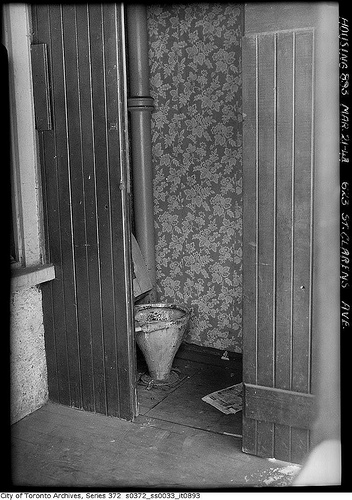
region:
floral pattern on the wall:
[166, 147, 236, 266]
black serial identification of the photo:
[0, 490, 214, 498]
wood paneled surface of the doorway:
[266, 277, 321, 405]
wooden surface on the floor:
[70, 420, 202, 481]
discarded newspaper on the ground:
[201, 382, 239, 422]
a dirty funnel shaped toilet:
[133, 295, 192, 382]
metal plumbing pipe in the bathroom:
[109, 4, 179, 263]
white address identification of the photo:
[327, 16, 351, 334]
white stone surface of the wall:
[16, 309, 50, 403]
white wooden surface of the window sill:
[0, 264, 60, 287]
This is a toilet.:
[112, 267, 223, 400]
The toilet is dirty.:
[123, 283, 213, 397]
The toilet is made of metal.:
[126, 299, 197, 396]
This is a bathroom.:
[49, 70, 263, 350]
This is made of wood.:
[47, 157, 127, 363]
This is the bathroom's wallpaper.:
[156, 123, 242, 278]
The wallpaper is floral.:
[165, 117, 236, 283]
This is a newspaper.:
[194, 365, 267, 435]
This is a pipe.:
[119, 105, 164, 271]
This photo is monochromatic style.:
[24, 74, 293, 327]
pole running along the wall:
[125, 4, 160, 299]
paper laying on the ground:
[202, 375, 249, 421]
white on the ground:
[250, 456, 303, 489]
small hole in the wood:
[299, 281, 306, 291]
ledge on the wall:
[11, 256, 56, 290]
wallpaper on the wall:
[145, 4, 241, 352]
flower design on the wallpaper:
[148, 11, 247, 350]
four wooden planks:
[241, 33, 317, 455]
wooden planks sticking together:
[32, 6, 141, 419]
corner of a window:
[11, 248, 24, 266]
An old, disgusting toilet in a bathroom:
[126, 294, 196, 390]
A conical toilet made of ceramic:
[131, 300, 199, 405]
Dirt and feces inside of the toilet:
[135, 307, 190, 336]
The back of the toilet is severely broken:
[116, 228, 162, 299]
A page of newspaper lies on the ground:
[201, 373, 265, 425]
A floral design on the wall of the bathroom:
[150, 118, 240, 326]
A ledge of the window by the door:
[4, 262, 63, 303]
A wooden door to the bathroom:
[50, 184, 119, 366]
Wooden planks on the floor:
[35, 427, 225, 486]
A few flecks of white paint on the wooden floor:
[251, 460, 305, 482]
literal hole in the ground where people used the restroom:
[134, 303, 194, 379]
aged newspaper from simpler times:
[201, 383, 240, 415]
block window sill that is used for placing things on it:
[10, 264, 54, 292]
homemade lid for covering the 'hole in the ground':
[131, 231, 152, 299]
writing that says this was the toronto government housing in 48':
[338, 13, 348, 325]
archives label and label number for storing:
[0, 490, 200, 495]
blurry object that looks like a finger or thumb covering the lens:
[290, 0, 338, 486]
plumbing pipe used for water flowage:
[126, 2, 157, 303]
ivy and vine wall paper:
[148, 3, 243, 353]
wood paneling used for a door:
[240, 3, 318, 465]